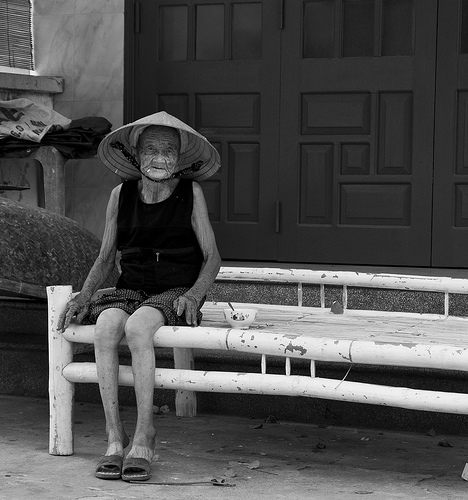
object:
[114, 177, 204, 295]
shirt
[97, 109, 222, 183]
hat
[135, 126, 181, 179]
head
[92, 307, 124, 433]
leg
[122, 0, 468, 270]
door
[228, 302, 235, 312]
spoon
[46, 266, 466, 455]
bench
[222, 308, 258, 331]
bowl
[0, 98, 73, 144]
newspaper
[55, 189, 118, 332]
right arm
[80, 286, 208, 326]
skirt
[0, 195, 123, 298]
basket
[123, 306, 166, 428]
leg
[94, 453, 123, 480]
shoes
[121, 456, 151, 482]
shoes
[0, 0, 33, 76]
window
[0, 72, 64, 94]
ledge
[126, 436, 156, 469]
foot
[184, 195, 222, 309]
left arm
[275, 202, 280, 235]
hinge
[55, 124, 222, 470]
person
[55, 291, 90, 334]
right hand